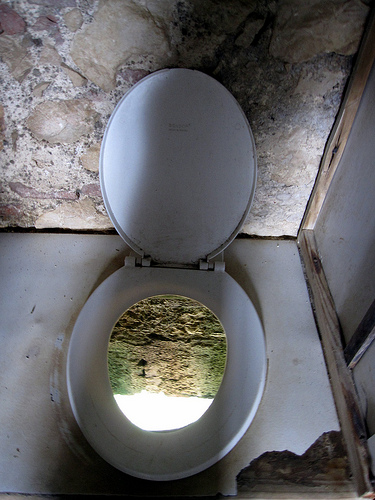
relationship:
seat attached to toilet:
[77, 339, 229, 450] [67, 144, 260, 450]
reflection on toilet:
[93, 111, 143, 229] [67, 144, 260, 450]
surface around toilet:
[24, 320, 71, 413] [67, 144, 260, 450]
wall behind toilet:
[97, 8, 168, 43] [67, 144, 260, 450]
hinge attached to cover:
[125, 252, 151, 270] [101, 281, 211, 422]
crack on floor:
[262, 444, 327, 494] [278, 325, 318, 448]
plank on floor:
[340, 327, 371, 359] [278, 325, 318, 448]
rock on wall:
[45, 0, 81, 40] [97, 8, 168, 43]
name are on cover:
[168, 121, 191, 133] [98, 65, 258, 268]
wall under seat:
[97, 8, 168, 43] [77, 339, 229, 450]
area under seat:
[118, 295, 208, 414] [77, 339, 229, 450]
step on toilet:
[108, 243, 232, 285] [67, 144, 260, 450]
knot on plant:
[129, 353, 147, 371] [118, 295, 208, 414]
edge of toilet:
[208, 264, 264, 303] [67, 144, 260, 450]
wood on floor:
[258, 445, 283, 476] [278, 325, 318, 448]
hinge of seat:
[152, 252, 211, 308] [77, 339, 229, 450]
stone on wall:
[73, 210, 116, 234] [97, 8, 168, 43]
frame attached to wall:
[299, 222, 326, 277] [97, 8, 168, 43]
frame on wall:
[299, 222, 326, 277] [97, 8, 168, 43]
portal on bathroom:
[103, 293, 231, 424] [27, 133, 322, 440]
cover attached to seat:
[98, 65, 258, 268] [77, 339, 229, 450]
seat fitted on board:
[77, 339, 229, 450] [163, 440, 262, 493]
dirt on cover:
[156, 227, 186, 253] [98, 65, 258, 268]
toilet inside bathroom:
[67, 144, 260, 450] [27, 133, 322, 440]